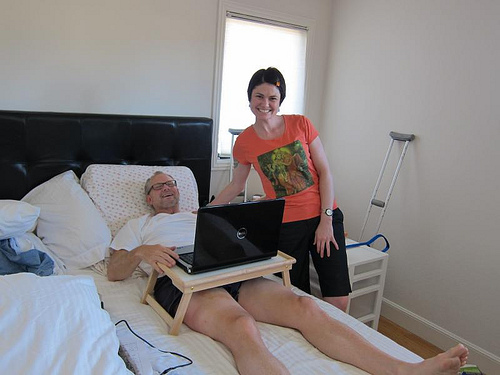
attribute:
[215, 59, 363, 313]
woman — light skinned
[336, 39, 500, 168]
wall — white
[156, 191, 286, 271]
laptop — black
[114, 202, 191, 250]
tee shirt — white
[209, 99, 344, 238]
shirt — orange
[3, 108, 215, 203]
bedframe — black, leather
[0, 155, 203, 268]
pillow — white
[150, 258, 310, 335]
bed desk — brown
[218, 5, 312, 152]
window — white, closed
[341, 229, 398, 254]
spectacle — blue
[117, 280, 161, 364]
sheet — white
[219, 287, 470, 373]
legs — apart